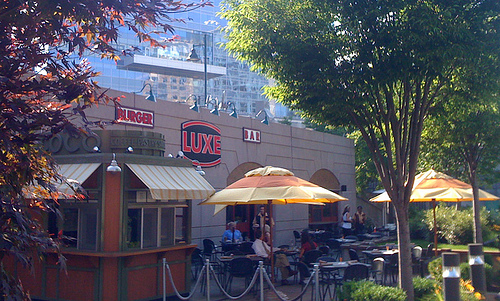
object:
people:
[252, 206, 275, 243]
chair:
[225, 256, 257, 297]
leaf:
[56, 253, 70, 278]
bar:
[162, 257, 167, 300]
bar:
[205, 258, 210, 300]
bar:
[258, 260, 265, 301]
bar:
[313, 265, 319, 301]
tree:
[214, 0, 500, 300]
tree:
[345, 70, 498, 247]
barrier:
[467, 240, 488, 300]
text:
[245, 130, 260, 141]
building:
[0, 70, 358, 300]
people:
[222, 222, 244, 244]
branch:
[438, 111, 498, 170]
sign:
[113, 105, 154, 129]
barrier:
[440, 248, 461, 300]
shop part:
[105, 161, 120, 299]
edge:
[311, 165, 344, 186]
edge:
[228, 158, 267, 165]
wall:
[28, 86, 354, 248]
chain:
[163, 264, 315, 301]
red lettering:
[182, 131, 221, 156]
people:
[251, 230, 298, 285]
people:
[299, 232, 318, 263]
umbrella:
[197, 165, 349, 284]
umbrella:
[369, 167, 500, 257]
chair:
[255, 252, 272, 283]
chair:
[301, 250, 323, 288]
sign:
[181, 120, 222, 168]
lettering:
[115, 107, 155, 128]